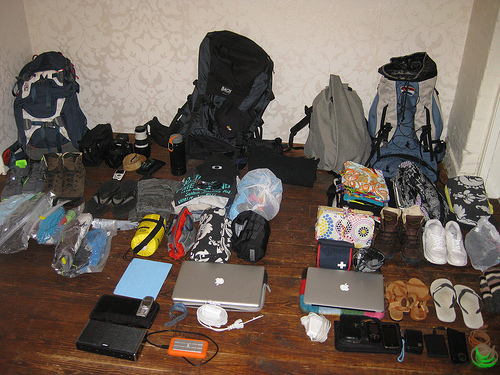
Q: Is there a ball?
A: No, there are no balls.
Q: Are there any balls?
A: No, there are no balls.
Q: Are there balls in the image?
A: No, there are no balls.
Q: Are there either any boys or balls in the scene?
A: No, there are no balls or boys.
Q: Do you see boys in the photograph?
A: No, there are no boys.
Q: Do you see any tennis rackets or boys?
A: No, there are no boys or tennis rackets.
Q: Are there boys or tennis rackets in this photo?
A: No, there are no boys or tennis rackets.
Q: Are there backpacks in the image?
A: Yes, there is a backpack.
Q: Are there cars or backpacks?
A: Yes, there is a backpack.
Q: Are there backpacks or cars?
A: Yes, there is a backpack.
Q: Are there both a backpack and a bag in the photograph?
A: Yes, there are both a backpack and a bag.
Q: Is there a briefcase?
A: No, there are no briefcases.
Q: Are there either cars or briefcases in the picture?
A: No, there are no briefcases or cars.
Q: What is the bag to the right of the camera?
A: The bag is a backpack.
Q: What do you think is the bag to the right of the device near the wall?
A: The bag is a backpack.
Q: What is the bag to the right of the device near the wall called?
A: The bag is a backpack.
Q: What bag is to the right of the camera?
A: The bag is a backpack.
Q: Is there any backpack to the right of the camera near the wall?
A: Yes, there is a backpack to the right of the camera.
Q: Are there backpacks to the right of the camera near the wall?
A: Yes, there is a backpack to the right of the camera.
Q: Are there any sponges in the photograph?
A: No, there are no sponges.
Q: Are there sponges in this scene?
A: No, there are no sponges.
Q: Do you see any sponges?
A: No, there are no sponges.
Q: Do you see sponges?
A: No, there are no sponges.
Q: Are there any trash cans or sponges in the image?
A: No, there are no sponges or trash cans.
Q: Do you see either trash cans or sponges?
A: No, there are no sponges or trash cans.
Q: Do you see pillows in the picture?
A: No, there are no pillows.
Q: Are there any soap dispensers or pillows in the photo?
A: No, there are no pillows or soap dispensers.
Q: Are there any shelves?
A: No, there are no shelves.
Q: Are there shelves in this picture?
A: No, there are no shelves.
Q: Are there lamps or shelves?
A: No, there are no shelves or lamps.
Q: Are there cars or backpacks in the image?
A: Yes, there is a backpack.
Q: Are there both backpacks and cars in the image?
A: No, there is a backpack but no cars.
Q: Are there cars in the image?
A: No, there are no cars.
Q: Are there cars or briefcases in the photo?
A: No, there are no cars or briefcases.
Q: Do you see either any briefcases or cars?
A: No, there are no cars or briefcases.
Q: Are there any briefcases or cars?
A: No, there are no cars or briefcases.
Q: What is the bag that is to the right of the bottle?
A: The bag is a backpack.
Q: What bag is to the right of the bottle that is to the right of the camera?
A: The bag is a backpack.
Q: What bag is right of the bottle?
A: The bag is a backpack.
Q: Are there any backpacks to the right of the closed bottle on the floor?
A: Yes, there is a backpack to the right of the bottle.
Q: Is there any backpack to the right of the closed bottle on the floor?
A: Yes, there is a backpack to the right of the bottle.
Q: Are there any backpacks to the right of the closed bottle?
A: Yes, there is a backpack to the right of the bottle.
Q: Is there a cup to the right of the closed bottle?
A: No, there is a backpack to the right of the bottle.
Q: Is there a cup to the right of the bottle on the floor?
A: No, there is a backpack to the right of the bottle.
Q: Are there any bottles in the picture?
A: Yes, there is a bottle.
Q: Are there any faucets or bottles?
A: Yes, there is a bottle.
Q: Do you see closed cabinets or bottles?
A: Yes, there is a closed bottle.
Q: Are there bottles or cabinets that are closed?
A: Yes, the bottle is closed.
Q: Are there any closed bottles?
A: Yes, there is a closed bottle.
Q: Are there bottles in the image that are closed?
A: Yes, there is a closed bottle.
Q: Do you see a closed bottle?
A: Yes, there is a closed bottle.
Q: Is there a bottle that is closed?
A: Yes, there is a bottle that is closed.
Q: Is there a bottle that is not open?
A: Yes, there is an closed bottle.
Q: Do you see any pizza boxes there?
A: No, there are no pizza boxes.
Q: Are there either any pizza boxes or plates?
A: No, there are no pizza boxes or plates.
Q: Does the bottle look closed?
A: Yes, the bottle is closed.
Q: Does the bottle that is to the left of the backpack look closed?
A: Yes, the bottle is closed.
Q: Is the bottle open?
A: No, the bottle is closed.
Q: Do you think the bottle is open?
A: No, the bottle is closed.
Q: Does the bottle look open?
A: No, the bottle is closed.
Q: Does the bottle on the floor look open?
A: No, the bottle is closed.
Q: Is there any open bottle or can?
A: No, there is a bottle but it is closed.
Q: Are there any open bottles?
A: No, there is a bottle but it is closed.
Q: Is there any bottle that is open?
A: No, there is a bottle but it is closed.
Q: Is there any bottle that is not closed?
A: No, there is a bottle but it is closed.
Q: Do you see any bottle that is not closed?
A: No, there is a bottle but it is closed.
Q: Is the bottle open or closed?
A: The bottle is closed.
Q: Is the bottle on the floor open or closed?
A: The bottle is closed.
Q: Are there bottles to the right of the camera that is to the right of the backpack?
A: Yes, there is a bottle to the right of the camera.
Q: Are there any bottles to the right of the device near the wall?
A: Yes, there is a bottle to the right of the camera.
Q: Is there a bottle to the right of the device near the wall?
A: Yes, there is a bottle to the right of the camera.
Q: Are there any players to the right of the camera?
A: No, there is a bottle to the right of the camera.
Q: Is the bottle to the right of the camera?
A: Yes, the bottle is to the right of the camera.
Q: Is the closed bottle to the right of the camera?
A: Yes, the bottle is to the right of the camera.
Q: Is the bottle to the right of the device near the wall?
A: Yes, the bottle is to the right of the camera.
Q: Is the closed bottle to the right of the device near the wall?
A: Yes, the bottle is to the right of the camera.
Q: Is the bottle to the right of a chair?
A: No, the bottle is to the right of the camera.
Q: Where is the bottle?
A: The bottle is on the floor.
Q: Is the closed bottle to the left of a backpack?
A: Yes, the bottle is to the left of a backpack.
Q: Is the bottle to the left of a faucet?
A: No, the bottle is to the left of a backpack.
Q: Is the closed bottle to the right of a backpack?
A: No, the bottle is to the left of a backpack.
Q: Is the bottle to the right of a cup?
A: No, the bottle is to the right of the backpack.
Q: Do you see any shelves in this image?
A: No, there are no shelves.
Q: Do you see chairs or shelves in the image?
A: No, there are no shelves or chairs.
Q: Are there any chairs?
A: No, there are no chairs.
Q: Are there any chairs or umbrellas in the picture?
A: No, there are no chairs or umbrellas.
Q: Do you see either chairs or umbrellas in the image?
A: No, there are no chairs or umbrellas.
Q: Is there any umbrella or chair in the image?
A: No, there are no chairs or umbrellas.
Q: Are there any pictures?
A: No, there are no pictures.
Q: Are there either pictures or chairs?
A: No, there are no pictures or chairs.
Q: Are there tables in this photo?
A: Yes, there is a table.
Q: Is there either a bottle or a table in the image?
A: Yes, there is a table.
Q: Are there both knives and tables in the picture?
A: No, there is a table but no knives.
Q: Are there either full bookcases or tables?
A: Yes, there is a full table.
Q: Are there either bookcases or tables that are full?
A: Yes, the table is full.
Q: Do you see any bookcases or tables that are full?
A: Yes, the table is full.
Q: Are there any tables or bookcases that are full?
A: Yes, the table is full.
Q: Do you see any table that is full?
A: Yes, there is a full table.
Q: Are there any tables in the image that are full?
A: Yes, there is a table that is full.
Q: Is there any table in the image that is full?
A: Yes, there is a table that is full.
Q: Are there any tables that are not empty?
A: Yes, there is an full table.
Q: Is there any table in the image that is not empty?
A: Yes, there is an full table.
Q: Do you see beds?
A: No, there are no beds.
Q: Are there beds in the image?
A: No, there are no beds.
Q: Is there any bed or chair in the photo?
A: No, there are no beds or chairs.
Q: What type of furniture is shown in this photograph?
A: The furniture is a table.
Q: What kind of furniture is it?
A: The piece of furniture is a table.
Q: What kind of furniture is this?
A: That is a table.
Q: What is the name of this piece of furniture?
A: That is a table.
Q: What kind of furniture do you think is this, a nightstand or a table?
A: That is a table.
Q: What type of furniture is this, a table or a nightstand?
A: That is a table.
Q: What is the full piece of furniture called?
A: The piece of furniture is a table.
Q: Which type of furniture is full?
A: The furniture is a table.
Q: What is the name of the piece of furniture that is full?
A: The piece of furniture is a table.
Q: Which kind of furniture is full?
A: The furniture is a table.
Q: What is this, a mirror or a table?
A: This is a table.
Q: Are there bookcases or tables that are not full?
A: No, there is a table but it is full.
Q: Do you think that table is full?
A: Yes, the table is full.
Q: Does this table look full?
A: Yes, the table is full.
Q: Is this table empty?
A: No, the table is full.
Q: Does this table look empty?
A: No, the table is full.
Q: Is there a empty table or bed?
A: No, there is a table but it is full.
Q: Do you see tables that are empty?
A: No, there is a table but it is full.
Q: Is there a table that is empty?
A: No, there is a table but it is full.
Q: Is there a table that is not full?
A: No, there is a table but it is full.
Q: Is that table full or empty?
A: The table is full.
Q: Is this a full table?
A: Yes, this is a full table.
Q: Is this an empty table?
A: No, this is a full table.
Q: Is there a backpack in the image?
A: Yes, there is a backpack.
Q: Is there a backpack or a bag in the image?
A: Yes, there is a backpack.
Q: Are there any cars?
A: No, there are no cars.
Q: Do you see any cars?
A: No, there are no cars.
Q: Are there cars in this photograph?
A: No, there are no cars.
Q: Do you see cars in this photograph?
A: No, there are no cars.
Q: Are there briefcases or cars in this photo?
A: No, there are no cars or briefcases.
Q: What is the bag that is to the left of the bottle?
A: The bag is a backpack.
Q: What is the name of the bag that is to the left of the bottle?
A: The bag is a backpack.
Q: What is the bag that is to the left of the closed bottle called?
A: The bag is a backpack.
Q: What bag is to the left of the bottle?
A: The bag is a backpack.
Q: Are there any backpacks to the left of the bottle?
A: Yes, there is a backpack to the left of the bottle.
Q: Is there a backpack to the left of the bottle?
A: Yes, there is a backpack to the left of the bottle.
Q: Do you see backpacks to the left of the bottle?
A: Yes, there is a backpack to the left of the bottle.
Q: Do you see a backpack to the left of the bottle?
A: Yes, there is a backpack to the left of the bottle.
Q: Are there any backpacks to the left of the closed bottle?
A: Yes, there is a backpack to the left of the bottle.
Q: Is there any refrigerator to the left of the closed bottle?
A: No, there is a backpack to the left of the bottle.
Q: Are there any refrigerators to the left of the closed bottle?
A: No, there is a backpack to the left of the bottle.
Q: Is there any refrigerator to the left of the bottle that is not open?
A: No, there is a backpack to the left of the bottle.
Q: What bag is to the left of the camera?
A: The bag is a backpack.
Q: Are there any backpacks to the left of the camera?
A: Yes, there is a backpack to the left of the camera.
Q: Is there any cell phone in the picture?
A: Yes, there is a cell phone.